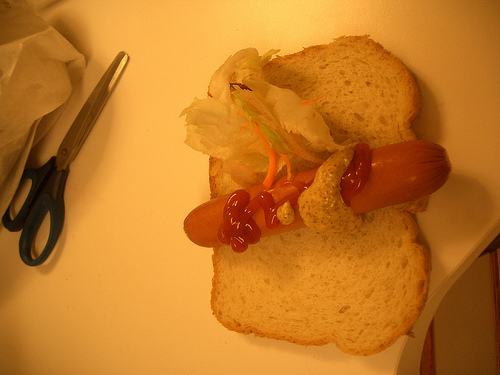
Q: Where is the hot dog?
A: On the bread.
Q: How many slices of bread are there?
A: One.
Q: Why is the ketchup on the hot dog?
A: For flavor.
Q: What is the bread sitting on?
A: The counter.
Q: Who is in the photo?
A: Nobody.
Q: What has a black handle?
A: The scissors.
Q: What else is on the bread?
A: Lettuce.